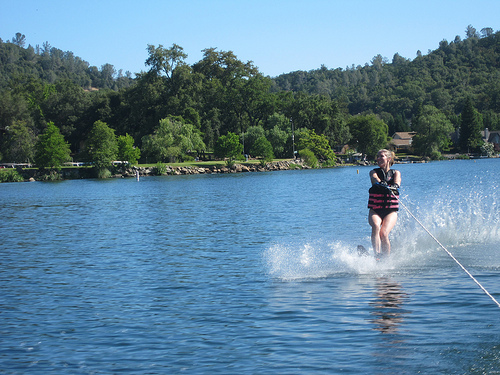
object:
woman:
[367, 149, 401, 261]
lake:
[0, 155, 500, 375]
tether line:
[391, 191, 500, 305]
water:
[448, 162, 499, 184]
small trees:
[141, 117, 195, 162]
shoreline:
[220, 167, 312, 173]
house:
[389, 130, 415, 154]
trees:
[213, 131, 247, 162]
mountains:
[0, 31, 500, 167]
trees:
[345, 114, 393, 161]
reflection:
[364, 277, 413, 374]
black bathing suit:
[368, 168, 399, 211]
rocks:
[276, 160, 311, 170]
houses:
[449, 128, 500, 153]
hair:
[377, 149, 399, 168]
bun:
[391, 151, 395, 157]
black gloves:
[390, 183, 399, 191]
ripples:
[126, 189, 170, 217]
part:
[267, 194, 314, 198]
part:
[169, 87, 225, 104]